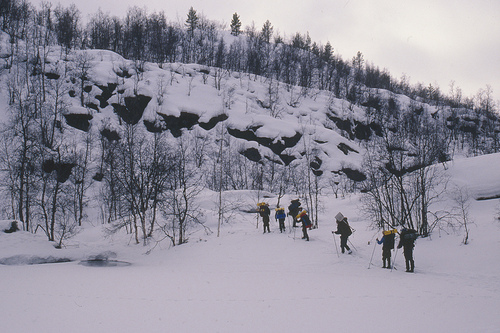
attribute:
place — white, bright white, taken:
[1, 17, 497, 333]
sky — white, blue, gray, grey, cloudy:
[99, 2, 499, 62]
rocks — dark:
[69, 84, 304, 154]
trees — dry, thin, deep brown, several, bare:
[92, 9, 366, 81]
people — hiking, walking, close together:
[256, 194, 421, 275]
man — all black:
[393, 223, 422, 276]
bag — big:
[399, 227, 421, 247]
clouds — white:
[264, 4, 496, 70]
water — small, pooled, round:
[77, 253, 138, 270]